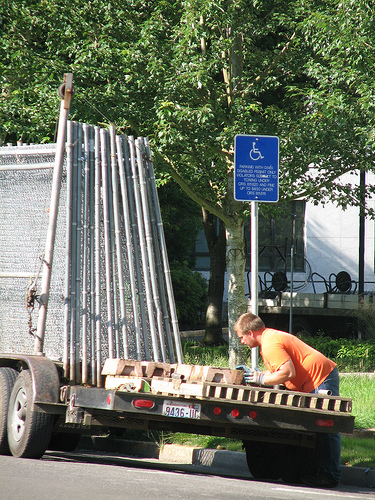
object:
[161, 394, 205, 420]
plate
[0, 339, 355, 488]
trailer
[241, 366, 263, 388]
gloves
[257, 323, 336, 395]
shirt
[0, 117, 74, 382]
fence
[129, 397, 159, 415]
lights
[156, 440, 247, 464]
curb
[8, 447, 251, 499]
street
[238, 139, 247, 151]
blue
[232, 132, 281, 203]
sign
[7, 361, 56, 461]
tires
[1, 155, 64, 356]
sections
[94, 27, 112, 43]
healthy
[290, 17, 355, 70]
leaves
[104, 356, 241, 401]
pallets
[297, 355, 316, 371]
orange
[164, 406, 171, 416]
numbers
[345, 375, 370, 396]
grass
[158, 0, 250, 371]
tree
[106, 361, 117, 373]
red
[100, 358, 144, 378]
bricks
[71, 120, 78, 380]
rows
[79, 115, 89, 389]
poles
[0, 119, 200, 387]
supplies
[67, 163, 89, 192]
metal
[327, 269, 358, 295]
chairs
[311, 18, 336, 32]
green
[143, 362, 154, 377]
yellow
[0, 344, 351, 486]
truck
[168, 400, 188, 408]
louisiana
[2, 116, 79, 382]
fencing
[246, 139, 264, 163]
handicapped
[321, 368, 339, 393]
jeans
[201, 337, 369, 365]
yard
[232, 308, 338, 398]
man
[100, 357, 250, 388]
cinder blocks